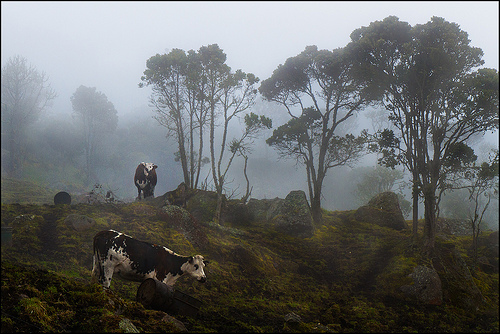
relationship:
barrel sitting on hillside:
[136, 276, 182, 310] [24, 198, 498, 332]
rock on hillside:
[267, 191, 309, 234] [24, 198, 498, 332]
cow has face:
[92, 231, 210, 294] [191, 259, 208, 281]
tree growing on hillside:
[263, 50, 373, 223] [24, 198, 498, 332]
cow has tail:
[92, 231, 210, 294] [91, 243, 97, 275]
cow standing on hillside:
[92, 231, 210, 294] [24, 198, 498, 332]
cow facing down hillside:
[92, 231, 210, 294] [24, 198, 498, 332]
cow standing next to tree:
[134, 162, 161, 199] [146, 52, 210, 193]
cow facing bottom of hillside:
[92, 231, 210, 294] [24, 198, 498, 332]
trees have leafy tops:
[142, 22, 497, 214] [148, 15, 495, 88]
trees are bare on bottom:
[142, 22, 497, 214] [170, 116, 499, 192]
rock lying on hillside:
[267, 191, 309, 234] [24, 198, 498, 332]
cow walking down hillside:
[92, 231, 210, 294] [24, 198, 498, 332]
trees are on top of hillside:
[142, 22, 497, 214] [24, 198, 498, 332]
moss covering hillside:
[15, 274, 103, 325] [24, 198, 498, 332]